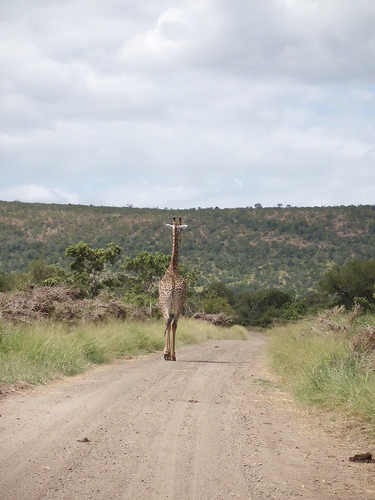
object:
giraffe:
[158, 217, 187, 361]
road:
[1, 325, 373, 496]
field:
[263, 305, 374, 425]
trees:
[0, 240, 374, 331]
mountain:
[1, 201, 374, 299]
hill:
[1, 279, 240, 333]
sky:
[1, 1, 373, 209]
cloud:
[107, 1, 373, 87]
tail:
[163, 279, 176, 337]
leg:
[170, 314, 180, 362]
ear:
[178, 222, 189, 230]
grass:
[2, 317, 249, 397]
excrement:
[77, 434, 90, 444]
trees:
[64, 240, 121, 302]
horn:
[169, 216, 179, 226]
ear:
[163, 223, 173, 229]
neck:
[168, 229, 179, 269]